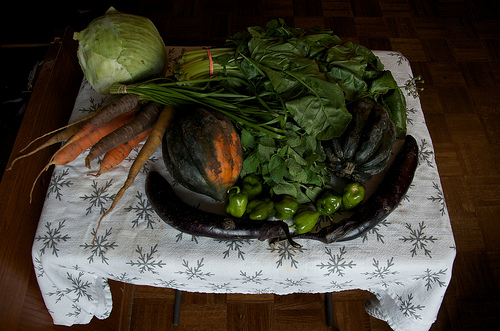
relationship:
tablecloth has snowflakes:
[72, 69, 460, 318] [396, 217, 445, 260]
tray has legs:
[162, 284, 345, 329] [169, 286, 341, 327]